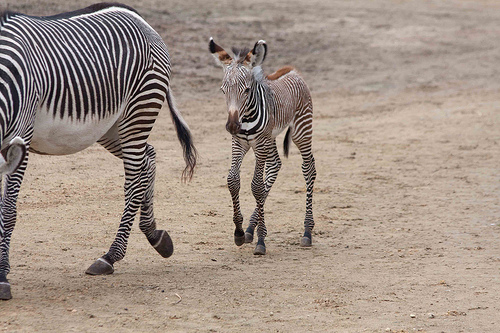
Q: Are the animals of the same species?
A: Yes, all the animals are zebras.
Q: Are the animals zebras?
A: Yes, all the animals are zebras.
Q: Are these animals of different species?
A: No, all the animals are zebras.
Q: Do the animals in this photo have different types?
A: No, all the animals are zebras.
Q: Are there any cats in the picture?
A: No, there are no cats.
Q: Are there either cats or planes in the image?
A: No, there are no cats or planes.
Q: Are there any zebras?
A: Yes, there is a zebra.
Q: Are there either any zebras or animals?
A: Yes, there is a zebra.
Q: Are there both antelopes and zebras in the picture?
A: No, there is a zebra but no antelopes.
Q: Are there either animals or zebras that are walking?
A: Yes, the zebra is walking.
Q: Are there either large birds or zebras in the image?
A: Yes, there is a large zebra.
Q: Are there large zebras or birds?
A: Yes, there is a large zebra.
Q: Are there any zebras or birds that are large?
A: Yes, the zebra is large.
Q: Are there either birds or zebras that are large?
A: Yes, the zebra is large.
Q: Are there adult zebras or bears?
A: Yes, there is an adult zebra.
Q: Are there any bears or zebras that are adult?
A: Yes, the zebra is adult.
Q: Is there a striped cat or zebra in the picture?
A: Yes, there is a striped zebra.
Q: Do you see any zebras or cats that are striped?
A: Yes, the zebra is striped.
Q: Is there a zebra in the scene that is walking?
A: Yes, there is a zebra that is walking.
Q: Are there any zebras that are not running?
A: Yes, there is a zebra that is walking.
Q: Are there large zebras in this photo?
A: Yes, there is a large zebra.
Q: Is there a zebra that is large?
A: Yes, there is a zebra that is large.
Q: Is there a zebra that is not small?
A: Yes, there is a large zebra.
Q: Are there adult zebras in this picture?
A: Yes, there is an adult zebra.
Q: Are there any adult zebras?
A: Yes, there is an adult zebra.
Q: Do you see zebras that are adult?
A: Yes, there is a zebra that is adult.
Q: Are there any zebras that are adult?
A: Yes, there is a zebra that is adult.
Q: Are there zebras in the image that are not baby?
A: Yes, there is a adult zebra.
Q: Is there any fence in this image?
A: No, there are no fences.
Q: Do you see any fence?
A: No, there are no fences.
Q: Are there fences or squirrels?
A: No, there are no fences or squirrels.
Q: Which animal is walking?
A: The animal is a zebra.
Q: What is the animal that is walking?
A: The animal is a zebra.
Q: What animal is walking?
A: The animal is a zebra.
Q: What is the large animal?
A: The animal is a zebra.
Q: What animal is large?
A: The animal is a zebra.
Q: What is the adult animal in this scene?
A: The animal is a zebra.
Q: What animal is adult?
A: The animal is a zebra.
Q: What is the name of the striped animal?
A: The animal is a zebra.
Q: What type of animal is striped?
A: The animal is a zebra.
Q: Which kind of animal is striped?
A: The animal is a zebra.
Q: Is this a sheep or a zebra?
A: This is a zebra.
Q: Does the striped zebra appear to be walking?
A: Yes, the zebra is walking.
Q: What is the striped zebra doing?
A: The zebra is walking.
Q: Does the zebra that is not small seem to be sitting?
A: No, the zebra is walking.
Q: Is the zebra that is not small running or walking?
A: The zebra is walking.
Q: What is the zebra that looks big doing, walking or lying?
A: The zebra is walking.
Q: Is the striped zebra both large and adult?
A: Yes, the zebra is large and adult.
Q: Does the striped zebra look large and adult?
A: Yes, the zebra is large and adult.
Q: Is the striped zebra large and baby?
A: No, the zebra is large but adult.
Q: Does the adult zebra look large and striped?
A: Yes, the zebra is large and striped.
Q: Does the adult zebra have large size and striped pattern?
A: Yes, the zebra is large and striped.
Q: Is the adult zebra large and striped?
A: Yes, the zebra is large and striped.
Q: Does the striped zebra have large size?
A: Yes, the zebra is large.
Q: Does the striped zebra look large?
A: Yes, the zebra is large.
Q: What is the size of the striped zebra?
A: The zebra is large.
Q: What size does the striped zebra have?
A: The zebra has large size.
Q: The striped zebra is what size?
A: The zebra is large.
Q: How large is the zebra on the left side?
A: The zebra is large.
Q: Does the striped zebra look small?
A: No, the zebra is large.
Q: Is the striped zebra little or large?
A: The zebra is large.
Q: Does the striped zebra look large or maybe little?
A: The zebra is large.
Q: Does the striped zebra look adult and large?
A: Yes, the zebra is adult and large.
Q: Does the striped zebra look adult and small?
A: No, the zebra is adult but large.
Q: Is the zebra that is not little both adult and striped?
A: Yes, the zebra is adult and striped.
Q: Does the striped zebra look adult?
A: Yes, the zebra is adult.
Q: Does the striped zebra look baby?
A: No, the zebra is adult.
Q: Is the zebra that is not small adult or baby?
A: The zebra is adult.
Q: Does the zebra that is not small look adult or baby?
A: The zebra is adult.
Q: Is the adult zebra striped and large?
A: Yes, the zebra is striped and large.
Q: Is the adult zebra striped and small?
A: No, the zebra is striped but large.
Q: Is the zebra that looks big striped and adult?
A: Yes, the zebra is striped and adult.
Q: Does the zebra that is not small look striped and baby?
A: No, the zebra is striped but adult.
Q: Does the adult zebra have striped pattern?
A: Yes, the zebra is striped.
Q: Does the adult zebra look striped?
A: Yes, the zebra is striped.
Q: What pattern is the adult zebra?
A: The zebra is striped.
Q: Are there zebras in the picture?
A: Yes, there are zebras.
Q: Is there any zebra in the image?
A: Yes, there are zebras.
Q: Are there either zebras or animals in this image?
A: Yes, there are zebras.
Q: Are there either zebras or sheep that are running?
A: Yes, the zebras are running.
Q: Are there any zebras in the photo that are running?
A: Yes, there are zebras that are running.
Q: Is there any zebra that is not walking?
A: Yes, there are zebras that are running.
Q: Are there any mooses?
A: No, there are no mooses.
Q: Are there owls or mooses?
A: No, there are no mooses or owls.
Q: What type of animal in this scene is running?
A: The animal is zebras.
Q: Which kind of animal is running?
A: The animal is zebras.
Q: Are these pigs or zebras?
A: These are zebras.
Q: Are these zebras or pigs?
A: These are zebras.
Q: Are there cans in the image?
A: No, there are no cans.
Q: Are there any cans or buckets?
A: No, there are no cans or buckets.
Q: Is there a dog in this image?
A: No, there are no dogs.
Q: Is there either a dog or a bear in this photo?
A: No, there are no dogs or bears.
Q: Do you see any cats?
A: No, there are no cats.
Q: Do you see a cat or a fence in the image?
A: No, there are no cats or fences.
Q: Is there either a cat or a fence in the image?
A: No, there are no cats or fences.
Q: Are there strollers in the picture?
A: No, there are no strollers.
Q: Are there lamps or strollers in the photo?
A: No, there are no strollers or lamps.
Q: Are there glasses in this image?
A: No, there are no glasses.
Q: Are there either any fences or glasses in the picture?
A: No, there are no glasses or fences.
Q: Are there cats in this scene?
A: No, there are no cats.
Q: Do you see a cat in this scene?
A: No, there are no cats.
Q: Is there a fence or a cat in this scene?
A: No, there are no cats or fences.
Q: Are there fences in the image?
A: No, there are no fences.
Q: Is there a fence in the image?
A: No, there are no fences.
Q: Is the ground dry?
A: Yes, the ground is dry.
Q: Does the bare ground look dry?
A: Yes, the ground is dry.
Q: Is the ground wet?
A: No, the ground is dry.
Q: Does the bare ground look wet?
A: No, the ground is dry.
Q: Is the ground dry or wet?
A: The ground is dry.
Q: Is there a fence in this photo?
A: No, there are no fences.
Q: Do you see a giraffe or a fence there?
A: No, there are no fences or giraffes.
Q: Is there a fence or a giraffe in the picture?
A: No, there are no fences or giraffes.